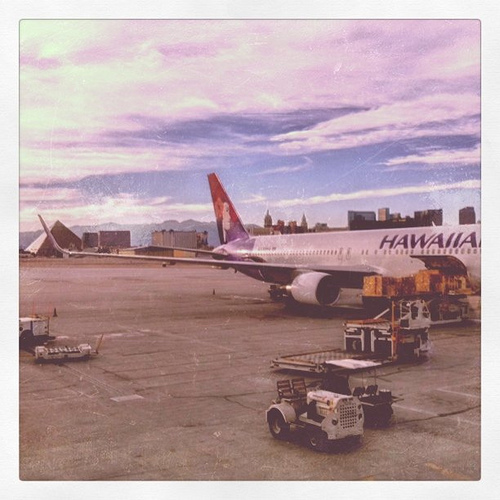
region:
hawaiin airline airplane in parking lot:
[379, 228, 481, 252]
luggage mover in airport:
[267, 381, 362, 449]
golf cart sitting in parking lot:
[332, 355, 404, 427]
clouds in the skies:
[52, 65, 261, 174]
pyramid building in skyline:
[33, 209, 77, 269]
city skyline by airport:
[260, 198, 482, 225]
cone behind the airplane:
[207, 282, 219, 303]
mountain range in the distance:
[110, 213, 206, 227]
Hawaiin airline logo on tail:
[205, 178, 244, 243]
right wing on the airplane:
[26, 206, 308, 303]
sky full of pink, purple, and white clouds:
[21, 18, 479, 227]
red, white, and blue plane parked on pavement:
[36, 171, 483, 319]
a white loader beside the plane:
[273, 293, 435, 371]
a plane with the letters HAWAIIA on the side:
[203, 172, 483, 309]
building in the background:
[28, 206, 478, 248]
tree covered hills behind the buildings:
[20, 218, 225, 245]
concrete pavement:
[20, 266, 477, 476]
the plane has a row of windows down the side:
[35, 170, 477, 312]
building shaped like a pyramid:
[24, 216, 83, 256]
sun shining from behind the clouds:
[49, 196, 171, 226]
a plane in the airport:
[31, 163, 480, 318]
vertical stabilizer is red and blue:
[198, 167, 253, 247]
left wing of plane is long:
[31, 206, 303, 284]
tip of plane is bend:
[29, 200, 110, 272]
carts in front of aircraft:
[250, 286, 457, 456]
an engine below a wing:
[264, 270, 346, 317]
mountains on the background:
[22, 210, 253, 263]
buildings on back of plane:
[241, 198, 478, 250]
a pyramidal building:
[20, 206, 88, 266]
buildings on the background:
[81, 223, 206, 260]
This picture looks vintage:
[47, 38, 458, 401]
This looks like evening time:
[49, 84, 427, 458]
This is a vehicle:
[256, 364, 370, 459]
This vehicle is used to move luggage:
[246, 372, 382, 487]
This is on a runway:
[29, 258, 466, 499]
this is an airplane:
[215, 188, 488, 336]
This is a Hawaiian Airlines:
[363, 224, 496, 269]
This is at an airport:
[41, 196, 413, 438]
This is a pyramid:
[28, 221, 93, 256]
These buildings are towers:
[307, 198, 449, 231]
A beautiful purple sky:
[161, 31, 336, 113]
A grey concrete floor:
[69, 408, 221, 453]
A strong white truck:
[265, 381, 368, 451]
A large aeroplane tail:
[203, 171, 250, 239]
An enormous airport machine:
[356, 268, 475, 298]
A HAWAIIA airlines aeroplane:
[371, 231, 482, 254]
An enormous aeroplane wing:
[34, 212, 158, 286]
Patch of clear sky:
[288, 163, 383, 193]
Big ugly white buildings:
[149, 224, 209, 249]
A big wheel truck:
[263, 400, 295, 443]